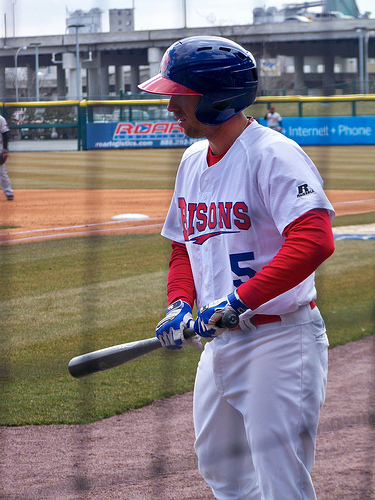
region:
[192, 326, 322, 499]
a pair of white pants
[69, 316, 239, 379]
a black bat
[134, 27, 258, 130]
a blue helmet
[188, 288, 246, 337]
a blue glove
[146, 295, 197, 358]
a blue glove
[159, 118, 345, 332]
a white shirt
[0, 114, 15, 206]
a person standing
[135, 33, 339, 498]
a person standing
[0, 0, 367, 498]
people playing baseball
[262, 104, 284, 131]
a person standing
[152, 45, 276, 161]
a baseball helmet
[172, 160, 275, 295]
bisons baseball jersey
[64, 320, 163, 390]
a baseball bat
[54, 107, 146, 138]
a baseball fence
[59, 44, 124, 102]
the bridge in the background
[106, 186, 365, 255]
yup the baseball finished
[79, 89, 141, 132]
blue sign on the thing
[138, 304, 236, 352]
blue gloves on the gloves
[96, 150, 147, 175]
the outfield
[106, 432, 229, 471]
the dirt near the batter box for the batter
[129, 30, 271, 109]
man wearing blue and red helmet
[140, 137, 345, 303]
man wearing white, orange and blue shirt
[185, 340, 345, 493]
man wearing white pants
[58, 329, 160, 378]
man carrying black bat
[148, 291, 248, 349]
man wearing blue and white batting gloves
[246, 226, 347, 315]
man wearing orange shirt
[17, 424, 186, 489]
brown dirt of baseball field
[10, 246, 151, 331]
green grass of baseball field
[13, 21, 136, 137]
gray building behind baseball field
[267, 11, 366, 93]
gray building behind baseball field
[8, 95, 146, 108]
Top of fence has a yellow metal guard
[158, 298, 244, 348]
Batter's gloves are blue, white, and black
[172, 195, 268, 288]
Batter is number five and plays for the Risons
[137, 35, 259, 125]
Batter's helmet is blue and red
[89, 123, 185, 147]
Roar has an advertisement on fence in background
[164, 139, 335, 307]
Batter's undershirt is long sleeved and red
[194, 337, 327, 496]
Batter's pants are white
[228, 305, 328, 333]
Batter is wearing a red belt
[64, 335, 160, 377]
Baseball bat is black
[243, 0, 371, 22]
Two level parking deck is behind batter in background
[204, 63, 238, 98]
part of a helmet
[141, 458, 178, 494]
part of the ground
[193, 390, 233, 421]
part of a trouser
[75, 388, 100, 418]
part of some grass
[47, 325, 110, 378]
edge of a club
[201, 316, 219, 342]
part of some glove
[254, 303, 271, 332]
part of a belt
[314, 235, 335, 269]
part of an elbow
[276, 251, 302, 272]
part of a sleeve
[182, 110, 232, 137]
edge of a helmet